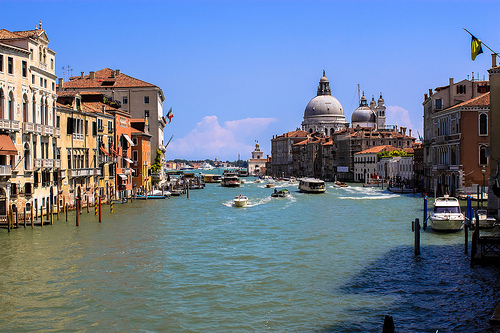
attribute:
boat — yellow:
[229, 190, 249, 206]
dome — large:
[301, 69, 348, 128]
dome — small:
[350, 94, 376, 125]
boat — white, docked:
[423, 193, 465, 235]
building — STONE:
[54, 65, 163, 178]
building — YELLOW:
[58, 92, 112, 209]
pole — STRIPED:
[103, 179, 110, 205]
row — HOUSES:
[3, 18, 160, 224]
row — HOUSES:
[8, 21, 168, 218]